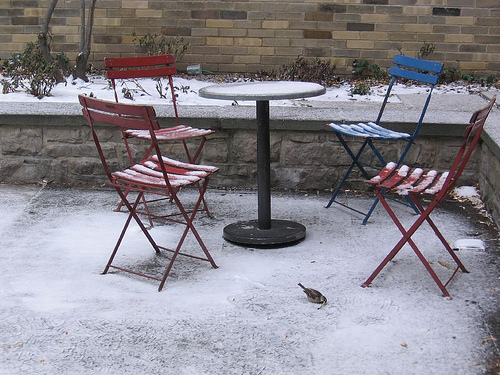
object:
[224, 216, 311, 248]
base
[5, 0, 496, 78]
building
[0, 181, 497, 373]
ground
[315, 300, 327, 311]
twig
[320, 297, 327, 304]
mouth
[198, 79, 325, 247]
table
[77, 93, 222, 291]
chair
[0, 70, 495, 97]
flower bed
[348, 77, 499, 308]
chair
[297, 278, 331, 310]
bird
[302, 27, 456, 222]
chair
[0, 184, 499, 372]
snow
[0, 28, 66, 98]
bush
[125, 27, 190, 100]
bush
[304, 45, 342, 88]
bush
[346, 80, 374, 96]
bush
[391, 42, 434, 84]
bush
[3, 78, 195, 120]
ledge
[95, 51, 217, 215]
chair